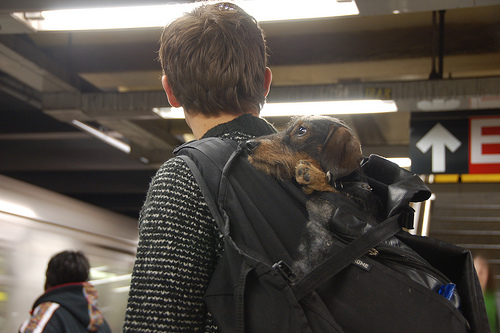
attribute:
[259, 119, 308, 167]
dog — sticking, popping, sad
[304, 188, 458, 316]
backpack — on, black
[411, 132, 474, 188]
arrow — white, up, pointing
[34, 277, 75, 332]
jacket — hooded, red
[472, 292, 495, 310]
shirt — green, background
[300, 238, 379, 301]
strap — black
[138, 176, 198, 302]
sweater — gray, white, black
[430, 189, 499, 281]
stairs — brown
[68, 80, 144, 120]
beam — hanging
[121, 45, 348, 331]
man — carrying, shirt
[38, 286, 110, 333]
coat — hooded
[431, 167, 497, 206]
stripe — yellow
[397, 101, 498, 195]
sign — large, exit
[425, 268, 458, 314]
pen — sticking out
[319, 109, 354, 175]
ear — floppy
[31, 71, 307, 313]
subway — scene